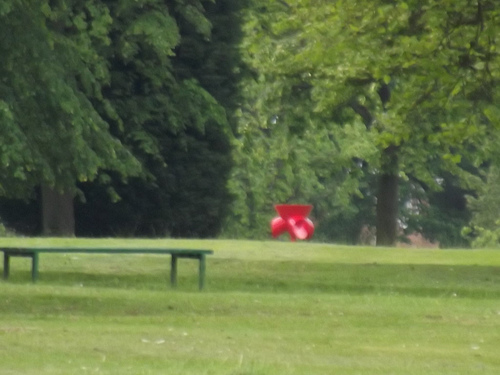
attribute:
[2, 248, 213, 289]
bench — green, flat, empty, long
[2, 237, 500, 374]
grass — green, healthy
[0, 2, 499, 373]
field — empty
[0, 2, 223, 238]
tree — large, tall, healthy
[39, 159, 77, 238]
trunk — brown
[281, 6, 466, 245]
tree — tall, healthy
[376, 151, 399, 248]
trunk — brown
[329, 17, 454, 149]
leaves — light green, green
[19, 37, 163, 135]
leaves — dark green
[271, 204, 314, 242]
object — red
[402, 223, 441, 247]
building — brown